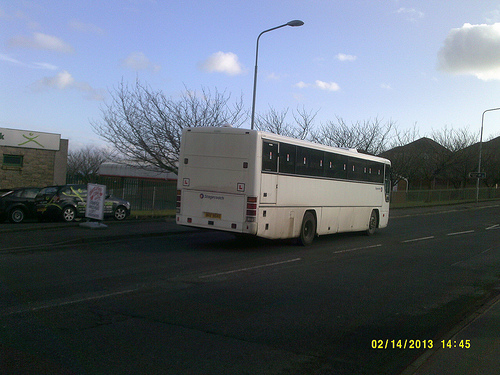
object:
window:
[318, 153, 332, 173]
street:
[2, 183, 496, 372]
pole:
[250, 35, 261, 130]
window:
[351, 157, 367, 180]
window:
[365, 161, 383, 181]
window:
[278, 143, 296, 175]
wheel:
[368, 208, 379, 236]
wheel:
[301, 210, 318, 247]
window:
[334, 153, 347, 180]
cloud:
[439, 23, 500, 81]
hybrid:
[35, 184, 131, 228]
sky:
[3, 2, 500, 76]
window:
[262, 136, 279, 177]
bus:
[175, 128, 392, 246]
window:
[304, 150, 321, 174]